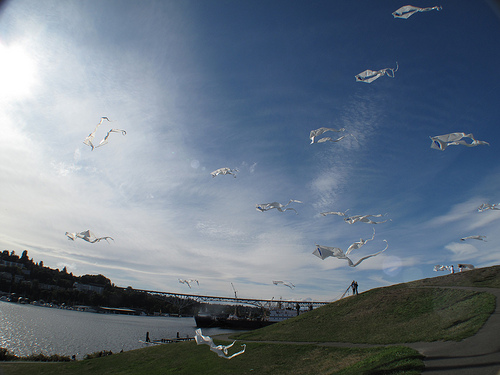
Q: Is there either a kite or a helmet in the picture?
A: Yes, there is a kite.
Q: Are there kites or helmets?
A: Yes, there is a kite.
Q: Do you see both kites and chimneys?
A: No, there is a kite but no chimneys.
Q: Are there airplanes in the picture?
A: No, there are no airplanes.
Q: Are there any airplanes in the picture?
A: No, there are no airplanes.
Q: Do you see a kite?
A: Yes, there is a kite.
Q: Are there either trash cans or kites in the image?
A: Yes, there is a kite.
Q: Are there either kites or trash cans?
A: Yes, there is a kite.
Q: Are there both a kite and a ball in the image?
A: No, there is a kite but no balls.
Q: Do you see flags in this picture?
A: No, there are no flags.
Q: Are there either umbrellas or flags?
A: No, there are no flags or umbrellas.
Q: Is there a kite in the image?
A: Yes, there is a kite.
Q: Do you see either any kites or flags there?
A: Yes, there is a kite.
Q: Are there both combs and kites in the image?
A: No, there is a kite but no combs.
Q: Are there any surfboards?
A: No, there are no surfboards.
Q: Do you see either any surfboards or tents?
A: No, there are no surfboards or tents.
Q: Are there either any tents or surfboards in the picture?
A: No, there are no surfboards or tents.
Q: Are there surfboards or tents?
A: No, there are no surfboards or tents.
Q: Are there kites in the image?
A: Yes, there is a kite.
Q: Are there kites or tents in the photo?
A: Yes, there is a kite.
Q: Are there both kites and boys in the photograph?
A: No, there is a kite but no boys.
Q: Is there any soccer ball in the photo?
A: No, there are no soccer balls.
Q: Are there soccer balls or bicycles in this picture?
A: No, there are no soccer balls or bicycles.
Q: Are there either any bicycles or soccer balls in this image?
A: No, there are no soccer balls or bicycles.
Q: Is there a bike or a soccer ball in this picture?
A: No, there are no soccer balls or bikes.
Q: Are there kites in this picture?
A: Yes, there is a kite.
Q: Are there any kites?
A: Yes, there is a kite.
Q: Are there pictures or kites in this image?
A: Yes, there is a kite.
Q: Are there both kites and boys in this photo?
A: No, there is a kite but no boys.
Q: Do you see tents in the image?
A: No, there are no tents.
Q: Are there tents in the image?
A: No, there are no tents.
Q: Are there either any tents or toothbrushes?
A: No, there are no tents or toothbrushes.